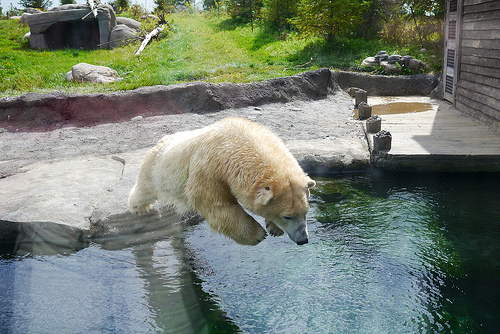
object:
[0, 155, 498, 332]
pool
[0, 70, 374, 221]
platform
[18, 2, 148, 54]
cave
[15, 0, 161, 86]
boulders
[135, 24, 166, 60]
tree branch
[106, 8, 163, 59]
pile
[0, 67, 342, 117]
embankment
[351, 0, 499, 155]
patio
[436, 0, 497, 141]
building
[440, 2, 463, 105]
door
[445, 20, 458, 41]
panels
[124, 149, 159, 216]
leg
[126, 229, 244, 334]
shadow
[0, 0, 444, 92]
grass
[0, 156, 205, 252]
rock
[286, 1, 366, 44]
trees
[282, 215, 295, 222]
eyes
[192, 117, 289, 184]
fur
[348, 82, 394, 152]
stones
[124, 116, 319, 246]
animal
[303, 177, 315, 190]
ear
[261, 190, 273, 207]
ear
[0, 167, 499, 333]
water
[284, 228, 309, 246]
snout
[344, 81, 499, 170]
deck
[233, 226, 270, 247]
claws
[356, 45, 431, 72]
rocks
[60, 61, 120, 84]
rock